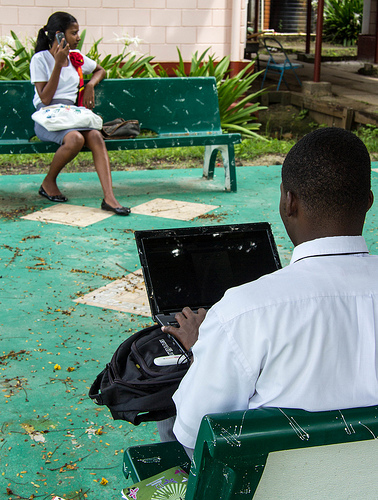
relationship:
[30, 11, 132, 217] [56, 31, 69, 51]
woman on phone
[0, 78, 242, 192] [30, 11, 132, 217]
bench with woman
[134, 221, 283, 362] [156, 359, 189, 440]
laptop on lap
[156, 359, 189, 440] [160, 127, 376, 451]
lap of man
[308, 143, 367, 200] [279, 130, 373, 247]
back of head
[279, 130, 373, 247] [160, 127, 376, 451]
head of man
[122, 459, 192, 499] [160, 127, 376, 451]
book next to man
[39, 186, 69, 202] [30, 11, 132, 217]
shoe of woman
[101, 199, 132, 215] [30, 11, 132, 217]
shoe of woman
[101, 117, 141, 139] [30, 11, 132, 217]
bag next to woman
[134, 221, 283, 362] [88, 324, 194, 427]
computer on top of backpack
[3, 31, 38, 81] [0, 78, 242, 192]
bush behind bench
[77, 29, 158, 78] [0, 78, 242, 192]
bush behind bench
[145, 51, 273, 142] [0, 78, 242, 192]
bush behind bench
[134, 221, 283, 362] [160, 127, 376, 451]
laptop used by man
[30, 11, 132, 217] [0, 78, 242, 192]
woman on bench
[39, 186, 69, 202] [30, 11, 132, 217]
shoe on woman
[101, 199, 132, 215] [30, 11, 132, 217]
shoe on woman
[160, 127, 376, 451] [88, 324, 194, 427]
man with backpack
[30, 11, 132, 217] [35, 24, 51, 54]
woman with ponytail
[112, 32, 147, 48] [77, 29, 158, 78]
flower on bush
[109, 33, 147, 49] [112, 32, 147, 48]
petals on flower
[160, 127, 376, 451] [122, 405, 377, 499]
man on bench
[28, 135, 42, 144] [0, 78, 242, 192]
hole in bench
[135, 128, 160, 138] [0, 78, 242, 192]
hole in bench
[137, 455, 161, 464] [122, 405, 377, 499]
scratch on bench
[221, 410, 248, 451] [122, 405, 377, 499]
scratch on bench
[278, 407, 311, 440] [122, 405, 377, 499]
scratch on bench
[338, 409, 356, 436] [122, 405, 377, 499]
scratch on bench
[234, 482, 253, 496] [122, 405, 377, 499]
scratch on bench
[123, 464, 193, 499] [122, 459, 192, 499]
cover of book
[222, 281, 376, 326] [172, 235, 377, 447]
seam in shirt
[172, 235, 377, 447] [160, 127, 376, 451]
shirt of man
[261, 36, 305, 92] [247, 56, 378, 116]
chair on porch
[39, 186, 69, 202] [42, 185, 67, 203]
shoe on foot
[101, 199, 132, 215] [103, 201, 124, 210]
shoe on foot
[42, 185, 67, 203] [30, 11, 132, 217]
foot on woman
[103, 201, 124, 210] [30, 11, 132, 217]
foot on woman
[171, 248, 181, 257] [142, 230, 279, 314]
spot on screen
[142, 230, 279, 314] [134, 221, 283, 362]
screen on laptop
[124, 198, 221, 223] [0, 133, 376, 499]
tile on ground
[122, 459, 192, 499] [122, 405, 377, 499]
book on bench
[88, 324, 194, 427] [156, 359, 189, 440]
backpack on lap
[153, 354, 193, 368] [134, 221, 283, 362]
jump drive in laptop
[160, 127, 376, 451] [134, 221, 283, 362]
man on laptop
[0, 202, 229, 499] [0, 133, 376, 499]
debris on ground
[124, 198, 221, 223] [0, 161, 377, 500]
tile on pathway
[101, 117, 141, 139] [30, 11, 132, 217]
bag of woman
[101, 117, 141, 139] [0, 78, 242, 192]
bag on bench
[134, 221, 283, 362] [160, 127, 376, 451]
laptop of man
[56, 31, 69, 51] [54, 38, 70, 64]
phone in hand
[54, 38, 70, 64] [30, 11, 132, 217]
hand of woman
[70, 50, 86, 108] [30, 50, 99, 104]
ribbon on shirt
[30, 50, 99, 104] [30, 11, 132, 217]
shirt of woman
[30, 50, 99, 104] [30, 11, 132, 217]
shirt worn by woman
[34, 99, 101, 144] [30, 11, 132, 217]
skirt worn by woman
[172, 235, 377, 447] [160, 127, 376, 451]
shirt worn by man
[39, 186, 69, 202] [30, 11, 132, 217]
shoe worn by woman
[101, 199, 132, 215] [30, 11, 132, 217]
shoe worn by woman